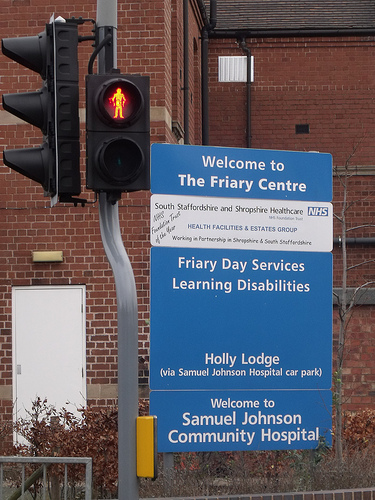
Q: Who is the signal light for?
A: Pedestrians.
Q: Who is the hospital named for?
A: Samuel Johnson.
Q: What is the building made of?
A: Brick.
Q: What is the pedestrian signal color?
A: Amber.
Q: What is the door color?
A: White.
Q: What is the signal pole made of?
A: Metal.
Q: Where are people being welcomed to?
A: The Friary Centre.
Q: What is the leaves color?
A: Brown.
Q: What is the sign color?
A: Blue and white.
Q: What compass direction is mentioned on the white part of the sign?
A: South.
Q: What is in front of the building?
A: A sign.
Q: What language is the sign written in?
A: English.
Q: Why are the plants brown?
A: They are dead.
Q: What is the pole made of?
A: Metal.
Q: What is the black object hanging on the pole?
A: Traffic light.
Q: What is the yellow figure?
A: A light to let walkers know to cross the road.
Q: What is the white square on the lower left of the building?
A: Door.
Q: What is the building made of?
A: Brick.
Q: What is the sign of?
A: Healthcare sign.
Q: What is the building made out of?
A: Brick.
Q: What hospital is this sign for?
A: Samuel Johnson Community Hospital.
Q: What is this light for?
A: Pedestrians.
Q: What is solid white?
A: The door.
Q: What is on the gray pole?
A: Traffic signal.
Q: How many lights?
A: One.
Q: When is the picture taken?
A: Daytime.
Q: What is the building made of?
A: Brick.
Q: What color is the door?
A: White.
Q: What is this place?
A: A hospital.